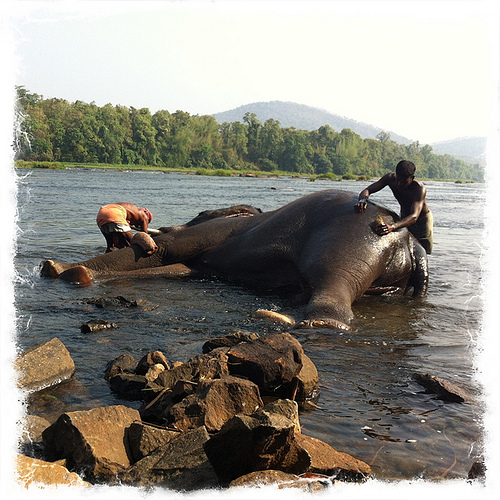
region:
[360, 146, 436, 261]
A person washing an elephant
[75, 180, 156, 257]
A person washing an elephant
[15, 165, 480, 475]
A large body of water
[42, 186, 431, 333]
An elephant in the water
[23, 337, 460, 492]
Some rocks in the water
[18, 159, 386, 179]
A grassy landscape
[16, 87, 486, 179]
A large forested area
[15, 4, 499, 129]
A clear, blue sky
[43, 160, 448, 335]
An elephant being bathed by two people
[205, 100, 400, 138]
A large forested hill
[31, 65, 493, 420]
an elephant in the water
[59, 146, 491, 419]
an elephant laying down in the water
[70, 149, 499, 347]
an elephant being washed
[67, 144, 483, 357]
an elephant being bathed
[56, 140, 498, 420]
two people bathing the elephant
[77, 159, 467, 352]
two people washing the elephant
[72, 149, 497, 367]
two people in the water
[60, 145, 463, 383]
people and elephant in the water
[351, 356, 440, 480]
a body of water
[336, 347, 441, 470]
a body of murky water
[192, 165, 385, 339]
elephant in the water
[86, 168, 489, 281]
elephant is on it's side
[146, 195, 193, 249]
elephant tusk is out of the water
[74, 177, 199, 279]
man bent over in the water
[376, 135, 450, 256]
man washing elephant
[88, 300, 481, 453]
rocks in the water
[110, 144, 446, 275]
two people washing the elephant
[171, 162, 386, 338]
elephant is wet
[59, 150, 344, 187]
shoreline along the water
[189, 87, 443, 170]
hill behind the mountain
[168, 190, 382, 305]
The elephant is laying in the water.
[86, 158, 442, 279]
Two men washing the elephant.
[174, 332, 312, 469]
Big rocks in the water.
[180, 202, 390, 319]
The elephant is wet.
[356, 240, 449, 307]
The elephant has a huge back side.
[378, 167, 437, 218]
The man is not wearing a shirt.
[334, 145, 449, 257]
The man is cleaning the elephant.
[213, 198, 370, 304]
The elephant is gray.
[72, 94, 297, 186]
The green trees on the other side of the water.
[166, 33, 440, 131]
The blue sky is clear.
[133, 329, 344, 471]
large brown rocks on river shore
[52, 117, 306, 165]
trees with green leaves on shore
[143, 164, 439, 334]
large elephant laying in water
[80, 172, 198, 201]
small ripples on surface of water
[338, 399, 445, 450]
small spots of white foam on water surface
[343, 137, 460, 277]
man washing large elephant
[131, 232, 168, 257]
brown elephant trunk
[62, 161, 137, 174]
grass growing on river shore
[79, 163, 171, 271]
person in red and yellow clothing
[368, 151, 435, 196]
man with black hair